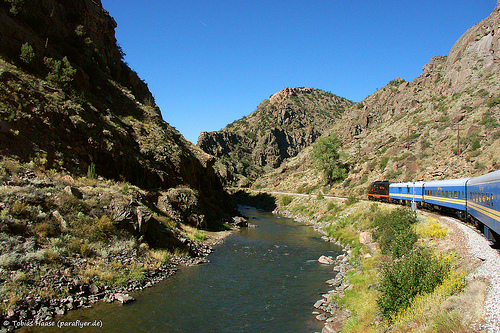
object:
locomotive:
[361, 178, 389, 201]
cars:
[362, 167, 499, 248]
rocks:
[305, 246, 351, 326]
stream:
[20, 199, 339, 333]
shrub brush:
[360, 205, 446, 325]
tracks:
[312, 194, 456, 219]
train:
[365, 170, 500, 251]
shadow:
[229, 185, 277, 214]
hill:
[1, 1, 233, 231]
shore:
[242, 189, 500, 333]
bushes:
[16, 36, 91, 100]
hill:
[192, 69, 360, 170]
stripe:
[387, 191, 498, 221]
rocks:
[136, 104, 236, 190]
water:
[11, 304, 314, 333]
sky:
[129, 1, 413, 69]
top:
[260, 82, 337, 113]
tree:
[305, 133, 347, 185]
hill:
[249, 5, 500, 182]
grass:
[322, 225, 381, 332]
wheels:
[456, 211, 471, 222]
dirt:
[439, 216, 500, 331]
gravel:
[472, 236, 499, 283]